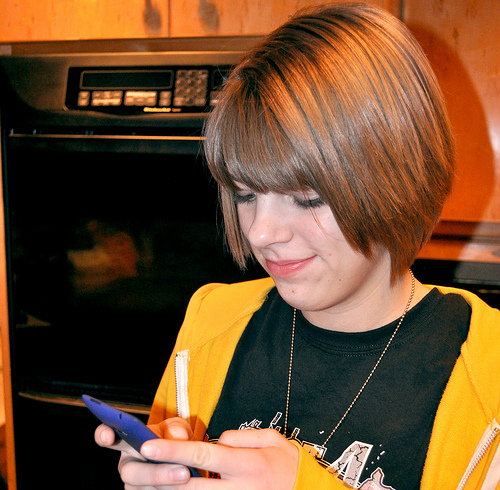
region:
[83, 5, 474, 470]
This is a woman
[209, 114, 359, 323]
This is a woman's face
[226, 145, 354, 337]
Face of a woman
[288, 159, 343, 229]
Eye of a woman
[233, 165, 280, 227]
Eye of a woman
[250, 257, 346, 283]
Nose of a woman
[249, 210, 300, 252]
Nose of a woman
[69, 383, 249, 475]
Phone of a woman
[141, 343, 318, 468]
Hand of a woman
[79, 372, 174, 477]
This is a purple phoone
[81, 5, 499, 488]
Teenage girl texting on purple cellphone.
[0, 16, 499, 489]
woman standing in the kitchen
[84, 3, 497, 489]
woman looking at her phone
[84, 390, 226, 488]
thin blue phone cradled in the hands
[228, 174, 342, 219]
eyes are looking down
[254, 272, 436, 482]
long chain around the neck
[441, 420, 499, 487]
white zipper on the yellow jacket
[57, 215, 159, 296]
reflection in the glas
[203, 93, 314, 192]
bangs laying on the forehead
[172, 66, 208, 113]
gray buttons on a keypad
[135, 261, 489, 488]
yellow jacket hanging open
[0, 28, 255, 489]
part of a black wall oven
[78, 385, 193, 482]
a blue cellphone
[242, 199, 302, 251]
the nose of a woman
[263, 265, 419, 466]
part of a chain necklace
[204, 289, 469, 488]
part of a black shirt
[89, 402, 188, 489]
the hand of a woman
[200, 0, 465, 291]
a woman's short hair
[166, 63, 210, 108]
a set of oven buttons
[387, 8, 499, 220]
part of a brown cabinet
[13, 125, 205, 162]
part of an oven door handle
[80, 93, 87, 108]
button on the stove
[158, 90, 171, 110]
button on the stove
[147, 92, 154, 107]
button on the stove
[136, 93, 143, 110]
button on the stove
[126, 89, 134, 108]
button on the stove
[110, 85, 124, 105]
button on the stove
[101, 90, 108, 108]
button on the stove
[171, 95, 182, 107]
button on the stove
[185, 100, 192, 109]
button on the stove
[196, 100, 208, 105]
button on the stove